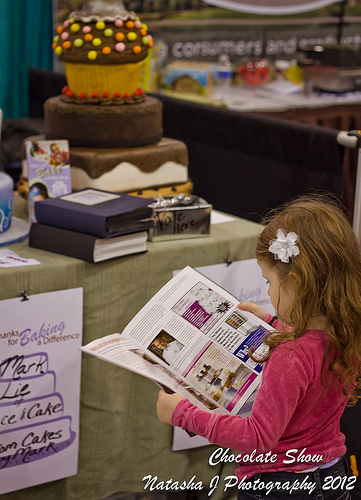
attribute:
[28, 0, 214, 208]
cake — large, brown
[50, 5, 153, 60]
frosting — chocolate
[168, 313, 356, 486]
shirt — pink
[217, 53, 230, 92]
bottle — water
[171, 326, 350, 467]
shirt — pink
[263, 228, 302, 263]
flower — white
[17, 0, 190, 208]
cake — large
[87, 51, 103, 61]
ball — yellow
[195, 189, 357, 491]
girl — reading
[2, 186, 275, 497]
table cloth — green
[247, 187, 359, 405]
hair — girl 